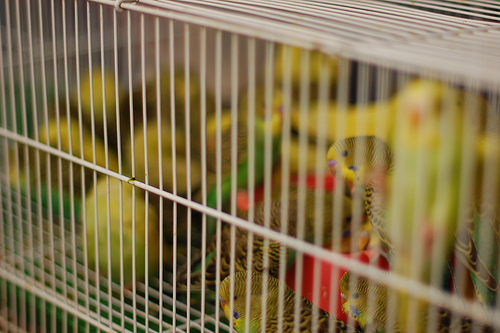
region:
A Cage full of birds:
[0, 0, 499, 332]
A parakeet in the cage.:
[215, 260, 352, 330]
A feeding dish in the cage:
[235, 165, 435, 320]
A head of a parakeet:
[320, 130, 395, 180]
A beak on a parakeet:
[220, 297, 237, 323]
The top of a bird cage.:
[95, 0, 495, 90]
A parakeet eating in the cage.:
[175, 186, 366, 281]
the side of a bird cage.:
[0, 0, 496, 330]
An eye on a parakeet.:
[340, 145, 350, 160]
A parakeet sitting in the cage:
[81, 170, 166, 290]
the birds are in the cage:
[107, 126, 419, 305]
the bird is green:
[185, 116, 338, 242]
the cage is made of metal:
[33, 63, 447, 233]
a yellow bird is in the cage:
[281, 63, 468, 143]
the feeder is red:
[249, 153, 374, 330]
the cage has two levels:
[25, 232, 142, 326]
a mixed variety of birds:
[40, 131, 462, 315]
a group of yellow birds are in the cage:
[40, 29, 251, 322]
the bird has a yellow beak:
[315, 144, 384, 174]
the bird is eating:
[239, 168, 493, 257]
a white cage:
[10, 0, 467, 327]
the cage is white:
[3, 3, 493, 331]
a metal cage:
[6, 0, 470, 330]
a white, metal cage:
[3, 6, 495, 331]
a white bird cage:
[6, 7, 498, 330]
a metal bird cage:
[3, 0, 494, 332]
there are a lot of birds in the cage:
[3, 0, 497, 330]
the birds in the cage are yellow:
[1, 0, 498, 332]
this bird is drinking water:
[166, 173, 374, 288]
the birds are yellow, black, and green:
[14, 49, 413, 329]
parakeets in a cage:
[18, 41, 446, 318]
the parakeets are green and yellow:
[16, 14, 476, 314]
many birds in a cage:
[12, 41, 472, 328]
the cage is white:
[26, 55, 498, 317]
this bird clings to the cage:
[353, 53, 481, 260]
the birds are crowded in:
[33, 50, 492, 296]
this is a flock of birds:
[61, 52, 493, 326]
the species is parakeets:
[33, 26, 443, 263]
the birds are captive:
[66, 65, 420, 297]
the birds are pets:
[23, 29, 418, 291]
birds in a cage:
[62, 48, 467, 318]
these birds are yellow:
[45, 59, 461, 306]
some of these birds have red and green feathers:
[64, 81, 460, 323]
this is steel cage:
[32, 31, 362, 302]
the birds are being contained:
[305, 129, 423, 326]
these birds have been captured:
[16, 33, 447, 264]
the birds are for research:
[37, 29, 264, 292]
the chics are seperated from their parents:
[224, 97, 438, 330]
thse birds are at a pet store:
[61, 46, 459, 309]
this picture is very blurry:
[42, 29, 465, 331]